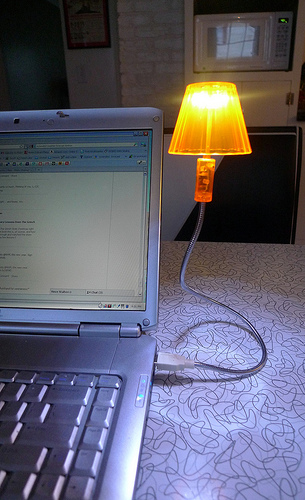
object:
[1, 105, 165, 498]
laptop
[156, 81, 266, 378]
lamp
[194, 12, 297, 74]
microwave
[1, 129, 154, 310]
screen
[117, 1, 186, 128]
bricks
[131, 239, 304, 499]
surface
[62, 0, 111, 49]
poster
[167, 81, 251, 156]
shade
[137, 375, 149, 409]
lights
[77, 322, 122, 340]
hinge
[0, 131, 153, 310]
icons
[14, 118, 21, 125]
camera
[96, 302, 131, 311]
icons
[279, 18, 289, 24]
green lights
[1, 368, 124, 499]
keyboard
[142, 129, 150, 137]
x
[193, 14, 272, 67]
reflection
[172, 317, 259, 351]
shadow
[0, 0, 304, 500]
room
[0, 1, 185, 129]
wall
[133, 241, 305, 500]
boomerangs